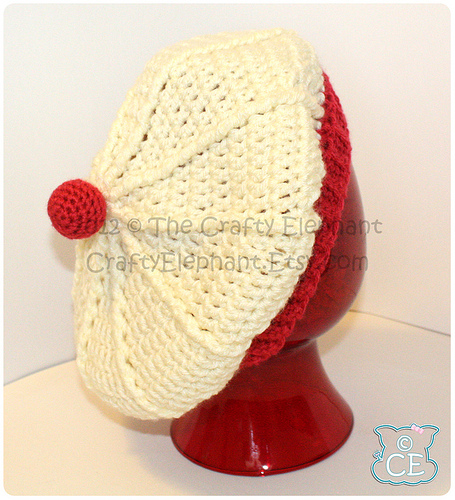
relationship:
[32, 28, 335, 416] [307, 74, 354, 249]
cap of yarn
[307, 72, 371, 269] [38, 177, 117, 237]
red a pom pom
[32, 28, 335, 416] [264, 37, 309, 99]
cap with crochet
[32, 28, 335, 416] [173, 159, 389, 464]
cap on mannequin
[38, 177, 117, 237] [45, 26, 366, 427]
pom pom on hat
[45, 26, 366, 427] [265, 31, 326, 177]
hat red crocheted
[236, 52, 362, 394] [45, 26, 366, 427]
border on hat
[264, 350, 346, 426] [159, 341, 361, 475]
glare on neck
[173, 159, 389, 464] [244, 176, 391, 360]
mannequin red head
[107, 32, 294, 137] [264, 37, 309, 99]
clit in crochet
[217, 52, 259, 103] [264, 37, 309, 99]
row of crochet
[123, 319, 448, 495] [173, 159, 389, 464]
shadow from mannequin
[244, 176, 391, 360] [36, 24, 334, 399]
head woven cover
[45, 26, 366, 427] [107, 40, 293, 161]
hat been knitted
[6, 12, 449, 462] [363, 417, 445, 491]
photo contains watermark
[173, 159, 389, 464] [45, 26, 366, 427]
mannequin wearing hat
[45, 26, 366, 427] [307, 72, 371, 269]
hat has red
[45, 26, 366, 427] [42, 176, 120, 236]
hat has ball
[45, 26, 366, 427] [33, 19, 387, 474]
hat on display